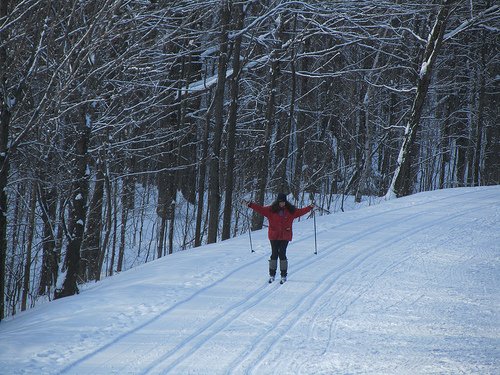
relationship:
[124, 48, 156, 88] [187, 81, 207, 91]
branches covered in snow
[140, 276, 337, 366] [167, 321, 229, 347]
street covered in snow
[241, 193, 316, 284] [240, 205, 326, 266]
person holding ski poles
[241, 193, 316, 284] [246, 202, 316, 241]
person wearing jacket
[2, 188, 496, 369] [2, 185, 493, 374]
ground covered in snow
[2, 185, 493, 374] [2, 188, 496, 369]
snow covering ground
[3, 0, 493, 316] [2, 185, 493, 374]
trees covering snow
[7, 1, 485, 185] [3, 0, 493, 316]
snow on trees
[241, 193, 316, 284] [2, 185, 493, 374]
person on snow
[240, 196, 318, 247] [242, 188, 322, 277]
jacket on person's body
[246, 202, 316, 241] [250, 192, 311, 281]
jacket on person's body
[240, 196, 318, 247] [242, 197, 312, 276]
jacket on person's body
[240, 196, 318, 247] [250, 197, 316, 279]
jacket on person's body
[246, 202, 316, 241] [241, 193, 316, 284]
jacket on person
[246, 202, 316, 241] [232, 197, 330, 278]
jacket on person's body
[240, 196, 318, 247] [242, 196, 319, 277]
jacket on person's body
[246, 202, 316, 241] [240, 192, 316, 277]
jacket on person's body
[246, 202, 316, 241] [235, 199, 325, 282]
jacket on person's body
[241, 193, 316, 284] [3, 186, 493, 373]
person skiing on hill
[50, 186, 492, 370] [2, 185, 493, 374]
ski tracks are in snow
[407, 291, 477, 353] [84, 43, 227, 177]
snow covered branches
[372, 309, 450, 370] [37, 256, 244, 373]
snow covered slope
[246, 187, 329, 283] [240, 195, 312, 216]
person with arms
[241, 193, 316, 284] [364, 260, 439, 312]
person on snow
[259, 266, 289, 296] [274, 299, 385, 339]
skis on snow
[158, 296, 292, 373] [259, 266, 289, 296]
marks of skis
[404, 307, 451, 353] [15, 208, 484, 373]
snow covered field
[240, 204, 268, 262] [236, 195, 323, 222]
pole on arm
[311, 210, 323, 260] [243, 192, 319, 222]
pole on arm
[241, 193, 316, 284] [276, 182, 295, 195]
person has hair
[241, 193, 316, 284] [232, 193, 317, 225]
person has arms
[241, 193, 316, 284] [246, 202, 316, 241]
person has jacket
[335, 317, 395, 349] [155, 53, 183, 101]
snow over branches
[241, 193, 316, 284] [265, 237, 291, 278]
person has pants